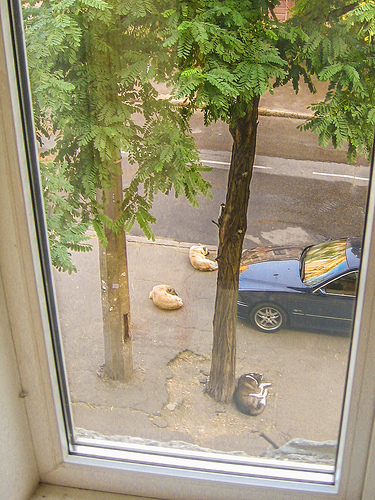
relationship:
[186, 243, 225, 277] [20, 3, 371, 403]
dog by tree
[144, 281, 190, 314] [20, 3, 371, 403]
dog by tree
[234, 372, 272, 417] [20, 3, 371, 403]
dog by tree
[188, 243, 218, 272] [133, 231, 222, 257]
dog by curb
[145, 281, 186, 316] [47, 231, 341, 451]
lab curled up on sidewalk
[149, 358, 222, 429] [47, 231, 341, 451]
crumbled surface on sidewalk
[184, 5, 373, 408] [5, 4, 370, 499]
tree outside of window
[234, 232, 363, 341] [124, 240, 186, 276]
car parked on sidewalk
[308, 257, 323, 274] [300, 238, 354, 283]
reflection on windshield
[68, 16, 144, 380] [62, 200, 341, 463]
pole on sidewalk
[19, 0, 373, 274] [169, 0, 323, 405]
leaves on tree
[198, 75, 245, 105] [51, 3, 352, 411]
leaves on tree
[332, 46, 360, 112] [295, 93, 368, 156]
leaves on tree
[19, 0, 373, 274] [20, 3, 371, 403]
leaves on tree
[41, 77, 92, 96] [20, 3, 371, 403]
leaves on tree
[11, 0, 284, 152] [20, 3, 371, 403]
leaves on tree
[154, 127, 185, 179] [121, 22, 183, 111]
leaves on tree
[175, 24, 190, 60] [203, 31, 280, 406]
leaves on tree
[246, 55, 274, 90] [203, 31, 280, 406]
leaves on tree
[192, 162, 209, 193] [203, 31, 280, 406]
leaves on tree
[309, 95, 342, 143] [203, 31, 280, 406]
leaves on tree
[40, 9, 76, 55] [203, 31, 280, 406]
leaves on tree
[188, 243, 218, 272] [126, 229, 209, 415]
dog on ground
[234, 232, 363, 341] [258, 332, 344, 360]
car on sidewalk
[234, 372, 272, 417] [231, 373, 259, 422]
dog are sleeping